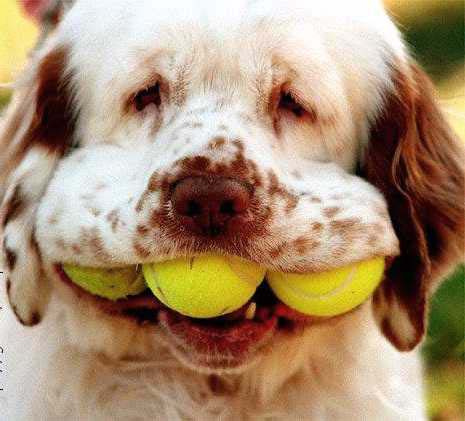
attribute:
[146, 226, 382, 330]
balls — green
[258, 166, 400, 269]
muzzle — white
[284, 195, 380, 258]
spots — brown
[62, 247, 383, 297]
balls — three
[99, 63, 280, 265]
dog — brown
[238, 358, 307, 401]
fur — white, long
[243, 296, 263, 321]
tooth — large, white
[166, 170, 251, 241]
nose — brown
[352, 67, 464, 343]
ear — long, brown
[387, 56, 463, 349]
ear — floppy, furry, brown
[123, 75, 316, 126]
eyes — black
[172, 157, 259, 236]
nose — brown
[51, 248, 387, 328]
tennis balls — yellow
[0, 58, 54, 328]
ear — floppy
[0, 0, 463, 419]
dog — brown, white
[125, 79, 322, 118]
eyes — open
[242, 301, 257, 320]
tooth — sharp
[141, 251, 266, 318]
ball — yellow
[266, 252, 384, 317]
tennis ball — three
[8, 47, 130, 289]
ears — brown, spotted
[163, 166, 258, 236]
nose — spotted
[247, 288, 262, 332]
tooth — white, bottom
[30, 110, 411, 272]
spots — brown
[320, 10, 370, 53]
fur — white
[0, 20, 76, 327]
ear — down turned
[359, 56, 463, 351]
ear — floppy, down turned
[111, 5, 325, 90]
forehead — white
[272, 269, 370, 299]
seam — white